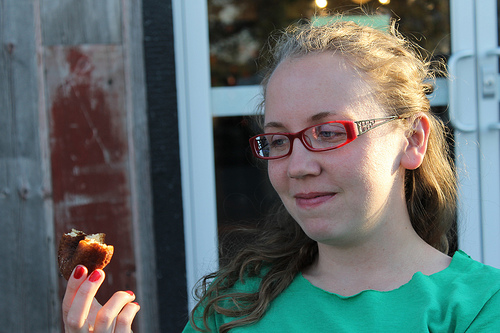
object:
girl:
[61, 22, 500, 332]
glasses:
[248, 115, 404, 160]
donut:
[57, 228, 113, 281]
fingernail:
[72, 264, 86, 279]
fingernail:
[87, 270, 104, 283]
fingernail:
[124, 289, 135, 296]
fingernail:
[131, 301, 141, 306]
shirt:
[182, 247, 499, 333]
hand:
[60, 265, 142, 333]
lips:
[290, 198, 341, 210]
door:
[169, 0, 499, 333]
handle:
[478, 47, 500, 134]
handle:
[445, 48, 477, 134]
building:
[0, 1, 500, 333]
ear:
[401, 112, 430, 170]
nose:
[286, 140, 323, 180]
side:
[356, 116, 406, 137]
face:
[264, 50, 410, 243]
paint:
[40, 0, 138, 333]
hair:
[189, 8, 459, 331]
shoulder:
[207, 261, 313, 293]